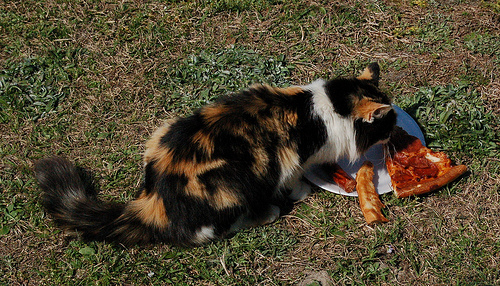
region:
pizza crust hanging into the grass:
[356, 158, 382, 239]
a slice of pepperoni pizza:
[380, 120, 470, 202]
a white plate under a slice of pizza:
[305, 85, 439, 203]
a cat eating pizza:
[28, 45, 411, 264]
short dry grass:
[10, 7, 496, 268]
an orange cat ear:
[355, 97, 391, 122]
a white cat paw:
[283, 180, 316, 202]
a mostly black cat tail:
[34, 151, 144, 249]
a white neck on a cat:
[306, 75, 354, 159]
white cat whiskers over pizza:
[380, 141, 400, 168]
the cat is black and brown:
[147, 112, 389, 283]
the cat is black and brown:
[61, 66, 496, 256]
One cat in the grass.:
[35, 57, 398, 254]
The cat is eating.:
[328, 79, 460, 201]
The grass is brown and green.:
[7, 7, 497, 272]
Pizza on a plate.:
[307, 102, 468, 225]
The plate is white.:
[311, 92, 430, 206]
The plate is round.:
[307, 92, 425, 204]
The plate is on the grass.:
[304, 82, 442, 204]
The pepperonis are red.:
[389, 133, 443, 188]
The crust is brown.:
[355, 155, 386, 225]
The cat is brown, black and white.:
[21, 49, 398, 251]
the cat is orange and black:
[127, 109, 308, 231]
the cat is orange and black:
[152, 77, 367, 241]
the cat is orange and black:
[187, 118, 434, 281]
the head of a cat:
[330, 57, 407, 153]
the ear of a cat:
[356, 95, 394, 121]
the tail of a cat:
[29, 146, 159, 247]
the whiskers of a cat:
[378, 137, 406, 172]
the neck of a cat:
[288, 72, 363, 162]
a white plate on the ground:
[301, 100, 427, 196]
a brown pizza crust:
[346, 157, 391, 229]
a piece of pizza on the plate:
[379, 120, 474, 201]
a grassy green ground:
[1, 0, 498, 284]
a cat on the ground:
[29, 57, 399, 253]